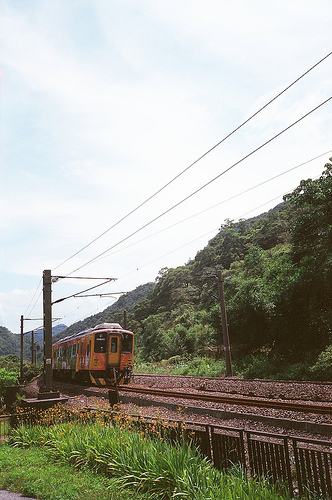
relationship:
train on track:
[45, 320, 141, 388] [29, 362, 331, 444]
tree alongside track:
[278, 161, 331, 356] [29, 362, 331, 444]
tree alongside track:
[226, 241, 285, 333] [29, 362, 331, 444]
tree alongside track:
[152, 268, 200, 307] [29, 362, 331, 444]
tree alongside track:
[187, 321, 216, 357] [29, 362, 331, 444]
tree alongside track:
[142, 314, 168, 356] [29, 362, 331, 444]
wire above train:
[48, 49, 331, 257] [45, 320, 141, 388]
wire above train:
[85, 97, 330, 272] [45, 320, 141, 388]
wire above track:
[48, 49, 331, 257] [29, 362, 331, 444]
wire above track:
[85, 97, 330, 272] [29, 362, 331, 444]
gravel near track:
[54, 376, 331, 436] [29, 362, 331, 444]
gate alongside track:
[71, 401, 331, 498] [29, 362, 331, 444]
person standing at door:
[110, 339, 118, 352] [107, 330, 123, 371]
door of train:
[107, 330, 123, 371] [45, 320, 141, 388]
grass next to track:
[4, 419, 294, 500] [29, 362, 331, 444]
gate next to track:
[71, 401, 331, 498] [29, 362, 331, 444]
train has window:
[45, 320, 141, 388] [70, 343, 79, 357]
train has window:
[45, 320, 141, 388] [64, 345, 72, 359]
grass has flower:
[4, 419, 294, 500] [190, 429, 195, 438]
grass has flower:
[4, 419, 294, 500] [149, 425, 154, 433]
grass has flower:
[4, 419, 294, 500] [120, 423, 125, 429]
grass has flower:
[4, 419, 294, 500] [97, 400, 102, 405]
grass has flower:
[4, 419, 294, 500] [69, 408, 75, 415]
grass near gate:
[4, 419, 294, 500] [71, 401, 331, 498]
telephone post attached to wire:
[39, 267, 56, 386] [48, 49, 331, 257]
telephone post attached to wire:
[39, 267, 56, 386] [85, 97, 330, 272]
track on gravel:
[29, 362, 331, 444] [54, 376, 331, 436]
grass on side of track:
[4, 419, 294, 500] [29, 362, 331, 444]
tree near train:
[278, 161, 331, 356] [45, 320, 141, 388]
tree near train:
[226, 241, 285, 333] [45, 320, 141, 388]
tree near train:
[187, 321, 216, 357] [45, 320, 141, 388]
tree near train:
[152, 268, 200, 307] [45, 320, 141, 388]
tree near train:
[148, 317, 182, 355] [45, 320, 141, 388]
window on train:
[70, 343, 79, 357] [45, 320, 141, 388]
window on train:
[64, 345, 72, 359] [45, 320, 141, 388]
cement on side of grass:
[1, 480, 35, 500] [4, 419, 294, 500]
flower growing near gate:
[190, 429, 195, 438] [71, 401, 331, 498]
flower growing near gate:
[149, 425, 154, 433] [71, 401, 331, 498]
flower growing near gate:
[120, 423, 125, 429] [71, 401, 331, 498]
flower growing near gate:
[97, 400, 102, 405] [71, 401, 331, 498]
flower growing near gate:
[69, 408, 75, 415] [71, 401, 331, 498]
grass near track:
[4, 419, 294, 500] [29, 362, 331, 444]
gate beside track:
[71, 401, 331, 498] [29, 362, 331, 444]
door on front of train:
[107, 330, 123, 371] [45, 320, 141, 388]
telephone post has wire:
[39, 267, 56, 386] [48, 49, 331, 257]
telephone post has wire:
[39, 267, 56, 386] [85, 97, 330, 272]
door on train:
[107, 330, 123, 371] [45, 320, 141, 388]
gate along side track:
[71, 401, 331, 498] [29, 362, 331, 444]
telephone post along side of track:
[39, 267, 56, 386] [29, 362, 331, 444]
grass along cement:
[4, 419, 294, 500] [1, 480, 35, 500]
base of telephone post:
[22, 386, 71, 411] [39, 267, 56, 386]